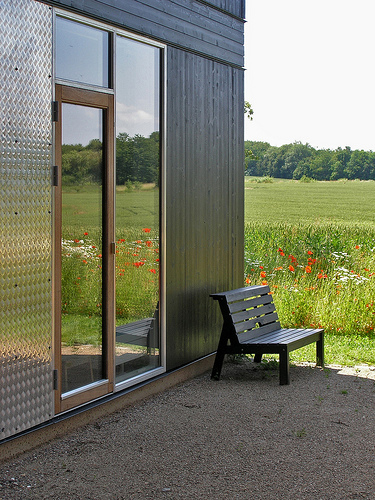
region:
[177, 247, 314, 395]
the bench is gray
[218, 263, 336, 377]
the bench is gray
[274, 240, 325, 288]
the flowers are orange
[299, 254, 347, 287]
the flowers are orange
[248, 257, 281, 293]
the flowers are orange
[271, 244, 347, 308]
the flowers are orange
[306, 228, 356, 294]
the flowers are orange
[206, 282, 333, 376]
bench by a building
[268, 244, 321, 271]
red flowers in the grass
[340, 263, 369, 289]
white flowers in the grass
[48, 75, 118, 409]
glass door of a building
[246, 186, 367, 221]
green grass of a pasture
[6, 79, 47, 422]
metal siding of a building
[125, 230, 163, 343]
reflection in the mirror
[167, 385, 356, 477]
concrete patio where bench is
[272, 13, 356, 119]
hazy sky in the distance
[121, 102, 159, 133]
white cloud in the reflection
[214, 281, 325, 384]
Dark wooden chair beside the house.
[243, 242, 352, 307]
Red flowers in the grass.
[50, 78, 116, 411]
Glass paneled door on side of house.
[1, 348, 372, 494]
Gray gravel on the ground.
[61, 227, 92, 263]
White flowers reflected in the grass.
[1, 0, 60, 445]
Metal panel on the side of the house.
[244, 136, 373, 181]
Green trees in the background.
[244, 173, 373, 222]
Green grass in the background.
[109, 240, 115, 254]
Metal handle on door.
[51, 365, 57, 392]
Black hinge on the door frame.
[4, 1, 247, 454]
home with metal, glass and wood surfaces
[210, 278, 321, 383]
brown wooden bench near corner of building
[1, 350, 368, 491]
gray gravel covering ground of home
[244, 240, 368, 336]
red and white flowers on long stems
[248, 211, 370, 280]
hedges in back of flowers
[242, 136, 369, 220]
meadow and trees away from house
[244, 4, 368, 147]
bright gray sky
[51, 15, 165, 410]
panes of glass in door and windows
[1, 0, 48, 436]
textured metal in diamond pattern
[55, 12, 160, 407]
windows reflecting pretty countryside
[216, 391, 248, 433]
part of a ground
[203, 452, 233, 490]
part of a ground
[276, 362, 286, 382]
part of a stand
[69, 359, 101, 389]
part of a window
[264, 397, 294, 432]
part of a floor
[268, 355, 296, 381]
part of a stool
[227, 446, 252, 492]
part of a shade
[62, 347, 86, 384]
part of a glass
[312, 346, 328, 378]
part of a stool